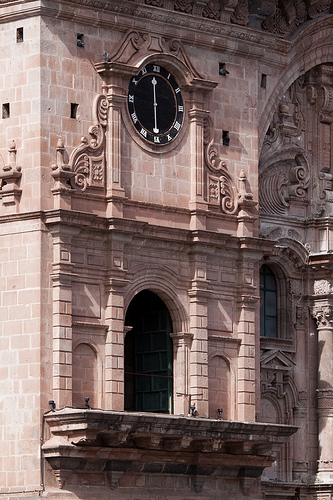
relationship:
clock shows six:
[125, 62, 185, 149] [151, 135, 162, 148]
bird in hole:
[217, 67, 230, 76] [217, 61, 227, 76]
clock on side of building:
[125, 62, 185, 149] [2, 2, 332, 499]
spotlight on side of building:
[81, 396, 94, 409] [2, 2, 332, 499]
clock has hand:
[125, 62, 185, 149] [148, 107, 160, 136]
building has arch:
[2, 2, 332, 499] [254, 60, 330, 479]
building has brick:
[2, 2, 332, 499] [51, 287, 71, 303]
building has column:
[2, 2, 332, 499] [94, 64, 140, 220]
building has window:
[2, 2, 332, 499] [121, 287, 187, 417]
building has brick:
[2, 2, 332, 499] [51, 299, 75, 316]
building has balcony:
[2, 2, 332, 499] [42, 408, 298, 471]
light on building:
[46, 399, 57, 415] [2, 2, 332, 499]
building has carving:
[2, 2, 332, 499] [51, 90, 110, 195]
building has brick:
[2, 2, 332, 499] [55, 337, 75, 354]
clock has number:
[125, 62, 185, 149] [176, 104, 185, 114]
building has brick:
[2, 2, 332, 499] [16, 347, 45, 363]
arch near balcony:
[254, 60, 330, 479] [42, 408, 298, 471]